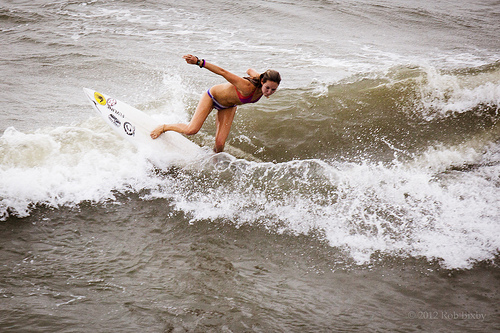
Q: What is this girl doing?
A: Surfing.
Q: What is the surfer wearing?
A: Bikini.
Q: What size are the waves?
A: Small.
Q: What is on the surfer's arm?
A: Bracelets.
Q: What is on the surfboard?
A: Stickers.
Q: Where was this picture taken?
A: Beach.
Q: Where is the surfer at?
A: Ocean.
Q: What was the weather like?
A: Overcast.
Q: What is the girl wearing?
A: A bikini.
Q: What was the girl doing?
A: Surfing.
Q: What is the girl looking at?
A: The water.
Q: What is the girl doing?
A: Surfing.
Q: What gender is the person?
A: Female.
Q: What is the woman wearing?
A: A bikini.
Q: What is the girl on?
A: Surfboard.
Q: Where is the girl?
A: Beach.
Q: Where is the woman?
A: In the water.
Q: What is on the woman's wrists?
A: Bracelets.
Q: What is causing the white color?
A: Oceans breaking.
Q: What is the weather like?
A: Sunny.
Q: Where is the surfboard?
A: In the water.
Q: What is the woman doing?
A: Surfing.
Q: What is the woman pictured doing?
A: Surfing.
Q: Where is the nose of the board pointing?
A: Left.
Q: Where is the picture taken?
A: Ocean.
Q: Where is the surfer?
A: In the water.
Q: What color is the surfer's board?
A: White.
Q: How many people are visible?
A: 1.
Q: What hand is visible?
A: Right.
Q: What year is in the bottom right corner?
A: 2012.